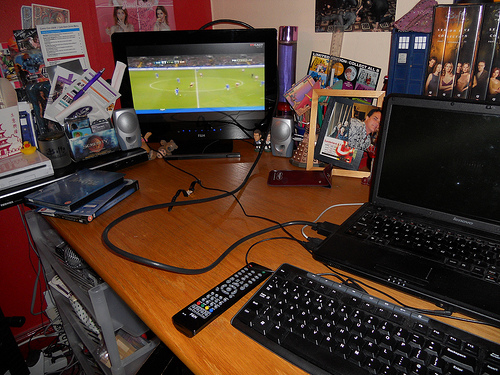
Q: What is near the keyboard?
A: Remote.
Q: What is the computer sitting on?
A: Desk.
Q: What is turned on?
A: The monitor.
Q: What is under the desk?
A: Plastic bin.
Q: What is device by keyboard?
A: Remote control.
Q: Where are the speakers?
A: Each side of monitor.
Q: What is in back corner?
A: Small tv.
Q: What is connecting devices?
A: Long black cord.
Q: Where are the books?
A: Behind monitor.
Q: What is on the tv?
A: Soccer game.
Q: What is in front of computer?
A: Keyboard.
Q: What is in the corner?
A: A tv.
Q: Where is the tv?
A: In the corner.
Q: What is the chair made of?
A: Metal.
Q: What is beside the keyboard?
A: A tv remote.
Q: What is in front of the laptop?
A: A keyboard.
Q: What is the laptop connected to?
A: A tv.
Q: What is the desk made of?
A: Wood.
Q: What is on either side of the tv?
A: Small silver speakers.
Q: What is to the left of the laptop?
A: A picture frame.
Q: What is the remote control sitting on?
A: The wood desk.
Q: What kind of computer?
A: Laptop.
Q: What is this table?
A: Desk.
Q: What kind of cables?
A: Computer.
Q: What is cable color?
A: Black.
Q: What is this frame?
A: Picture.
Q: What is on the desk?
A: Computers.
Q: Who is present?
A: No one.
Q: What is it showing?
A: Soccer.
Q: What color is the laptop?
A: Black.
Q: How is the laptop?
A: Off.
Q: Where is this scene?
A: Desk.